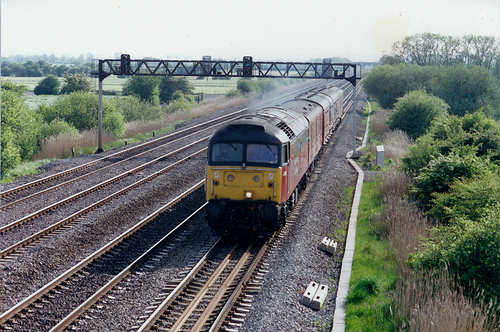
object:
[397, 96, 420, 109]
leaves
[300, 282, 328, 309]
ties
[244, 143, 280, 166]
window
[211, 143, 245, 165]
window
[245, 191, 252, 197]
light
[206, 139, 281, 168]
windshield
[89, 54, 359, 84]
pole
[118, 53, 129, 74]
traffic light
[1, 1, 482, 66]
sky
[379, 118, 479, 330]
straw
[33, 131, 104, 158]
straw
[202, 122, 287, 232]
front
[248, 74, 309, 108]
smoke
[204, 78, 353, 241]
train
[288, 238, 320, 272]
gravel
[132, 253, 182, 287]
gravel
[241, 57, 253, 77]
light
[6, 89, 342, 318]
tracks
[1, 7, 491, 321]
scene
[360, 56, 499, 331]
bushes